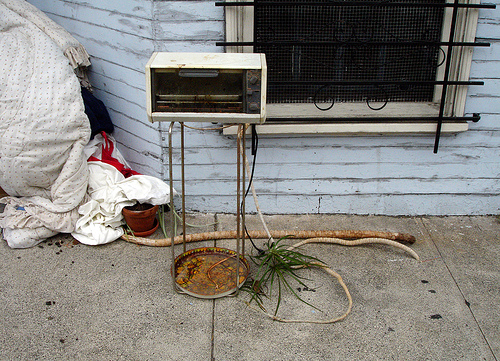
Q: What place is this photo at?
A: It is at the sidewalk.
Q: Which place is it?
A: It is a sidewalk.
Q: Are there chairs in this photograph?
A: No, there are no chairs.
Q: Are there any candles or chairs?
A: No, there are no chairs or candles.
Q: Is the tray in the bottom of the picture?
A: Yes, the tray is in the bottom of the image.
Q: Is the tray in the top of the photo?
A: No, the tray is in the bottom of the image.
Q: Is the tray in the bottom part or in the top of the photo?
A: The tray is in the bottom of the image.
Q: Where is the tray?
A: The tray is on the sidewalk.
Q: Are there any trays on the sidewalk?
A: Yes, there is a tray on the sidewalk.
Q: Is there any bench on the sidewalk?
A: No, there is a tray on the sidewalk.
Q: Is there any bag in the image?
A: No, there are no bags.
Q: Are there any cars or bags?
A: No, there are no bags or cars.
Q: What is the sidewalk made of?
A: The sidewalk is made of concrete.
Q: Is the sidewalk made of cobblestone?
A: No, the sidewalk is made of cement.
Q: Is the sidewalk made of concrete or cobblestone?
A: The sidewalk is made of concrete.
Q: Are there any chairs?
A: No, there are no chairs.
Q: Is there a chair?
A: No, there are no chairs.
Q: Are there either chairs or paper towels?
A: No, there are no chairs or paper towels.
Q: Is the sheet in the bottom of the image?
A: No, the sheet is in the top of the image.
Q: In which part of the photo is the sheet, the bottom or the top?
A: The sheet is in the top of the image.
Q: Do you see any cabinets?
A: No, there are no cabinets.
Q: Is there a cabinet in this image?
A: No, there are no cabinets.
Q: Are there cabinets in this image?
A: No, there are no cabinets.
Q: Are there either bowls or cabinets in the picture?
A: No, there are no cabinets or bowls.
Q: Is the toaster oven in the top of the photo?
A: Yes, the toaster oven is in the top of the image.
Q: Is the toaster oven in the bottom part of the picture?
A: No, the toaster oven is in the top of the image.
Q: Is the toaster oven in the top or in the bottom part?
A: The toaster oven is in the top of the image.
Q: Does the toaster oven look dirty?
A: Yes, the toaster oven is dirty.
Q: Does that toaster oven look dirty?
A: Yes, the toaster oven is dirty.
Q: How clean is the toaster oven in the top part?
A: The toaster oven is dirty.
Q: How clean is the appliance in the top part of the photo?
A: The toaster oven is dirty.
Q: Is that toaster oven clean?
A: No, the toaster oven is dirty.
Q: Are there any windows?
A: Yes, there is a window.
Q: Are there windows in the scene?
A: Yes, there is a window.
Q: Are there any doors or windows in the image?
A: Yes, there is a window.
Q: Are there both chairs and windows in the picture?
A: No, there is a window but no chairs.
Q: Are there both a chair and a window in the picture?
A: No, there is a window but no chairs.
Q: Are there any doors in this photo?
A: No, there are no doors.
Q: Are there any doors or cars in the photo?
A: No, there are no doors or cars.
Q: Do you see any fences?
A: No, there are no fences.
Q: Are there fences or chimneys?
A: No, there are no fences or chimneys.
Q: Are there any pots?
A: Yes, there is a pot.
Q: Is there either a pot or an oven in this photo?
A: Yes, there is a pot.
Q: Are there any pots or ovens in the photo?
A: Yes, there is a pot.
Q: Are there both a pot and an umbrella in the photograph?
A: No, there is a pot but no umbrellas.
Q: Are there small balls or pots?
A: Yes, there is a small pot.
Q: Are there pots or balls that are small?
A: Yes, the pot is small.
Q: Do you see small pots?
A: Yes, there is a small pot.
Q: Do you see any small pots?
A: Yes, there is a small pot.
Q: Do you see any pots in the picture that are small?
A: Yes, there is a pot that is small.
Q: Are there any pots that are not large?
A: Yes, there is a small pot.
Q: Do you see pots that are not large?
A: Yes, there is a small pot.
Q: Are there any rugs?
A: No, there are no rugs.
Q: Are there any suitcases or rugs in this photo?
A: No, there are no rugs or suitcases.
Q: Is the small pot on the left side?
A: Yes, the pot is on the left of the image.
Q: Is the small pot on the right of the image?
A: No, the pot is on the left of the image.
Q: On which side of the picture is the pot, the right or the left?
A: The pot is on the left of the image.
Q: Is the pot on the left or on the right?
A: The pot is on the left of the image.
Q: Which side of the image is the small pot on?
A: The pot is on the left of the image.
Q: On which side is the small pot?
A: The pot is on the left of the image.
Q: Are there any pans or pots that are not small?
A: No, there is a pot but it is small.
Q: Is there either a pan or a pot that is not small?
A: No, there is a pot but it is small.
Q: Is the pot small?
A: Yes, the pot is small.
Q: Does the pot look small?
A: Yes, the pot is small.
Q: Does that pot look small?
A: Yes, the pot is small.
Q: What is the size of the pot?
A: The pot is small.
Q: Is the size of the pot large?
A: No, the pot is small.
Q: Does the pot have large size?
A: No, the pot is small.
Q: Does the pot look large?
A: No, the pot is small.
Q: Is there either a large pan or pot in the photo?
A: No, there is a pot but it is small.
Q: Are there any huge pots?
A: No, there is a pot but it is small.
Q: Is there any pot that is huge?
A: No, there is a pot but it is small.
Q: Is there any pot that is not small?
A: No, there is a pot but it is small.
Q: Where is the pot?
A: The pot is on the sidewalk.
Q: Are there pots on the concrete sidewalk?
A: Yes, there is a pot on the sidewalk.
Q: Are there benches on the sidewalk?
A: No, there is a pot on the sidewalk.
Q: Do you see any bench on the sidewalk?
A: No, there is a pot on the sidewalk.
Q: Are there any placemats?
A: No, there are no placemats.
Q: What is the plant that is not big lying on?
A: The plant is lying on the sidewalk.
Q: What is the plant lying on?
A: The plant is lying on the sidewalk.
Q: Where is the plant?
A: The plant is on the sidewalk.